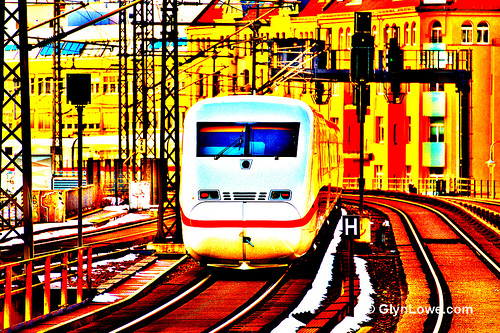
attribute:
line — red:
[177, 207, 322, 232]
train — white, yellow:
[170, 71, 358, 278]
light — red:
[196, 187, 220, 203]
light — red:
[266, 185, 294, 203]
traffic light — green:
[386, 39, 404, 103]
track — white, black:
[103, 262, 297, 331]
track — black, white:
[336, 192, 499, 331]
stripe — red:
[178, 195, 319, 230]